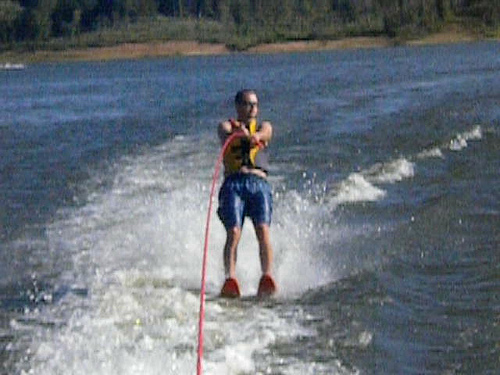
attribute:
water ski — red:
[251, 271, 278, 305]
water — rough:
[66, 169, 286, 371]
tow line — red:
[196, 128, 247, 373]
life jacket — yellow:
[245, 147, 267, 171]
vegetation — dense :
[2, 6, 485, 90]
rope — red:
[193, 130, 242, 373]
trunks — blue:
[212, 170, 275, 228]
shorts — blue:
[216, 175, 273, 229]